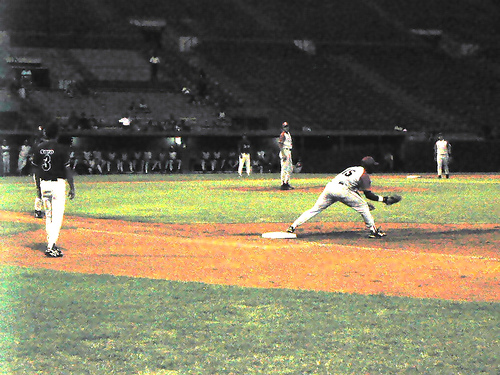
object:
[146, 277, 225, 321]
grassy part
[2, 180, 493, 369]
ball field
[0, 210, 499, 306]
dirt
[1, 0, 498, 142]
seating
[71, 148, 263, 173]
bench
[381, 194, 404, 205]
glove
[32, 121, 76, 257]
person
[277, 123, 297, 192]
person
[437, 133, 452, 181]
person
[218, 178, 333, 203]
mound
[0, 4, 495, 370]
baseball stadium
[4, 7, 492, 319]
photo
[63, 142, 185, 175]
team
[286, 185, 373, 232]
pants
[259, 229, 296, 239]
base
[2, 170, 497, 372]
ground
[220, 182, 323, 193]
part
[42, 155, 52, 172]
3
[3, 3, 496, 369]
baseball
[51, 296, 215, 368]
grass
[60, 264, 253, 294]
baseline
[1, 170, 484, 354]
field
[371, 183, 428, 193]
mound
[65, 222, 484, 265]
baseline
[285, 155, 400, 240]
ball player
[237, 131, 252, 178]
coach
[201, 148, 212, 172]
players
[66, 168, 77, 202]
arms